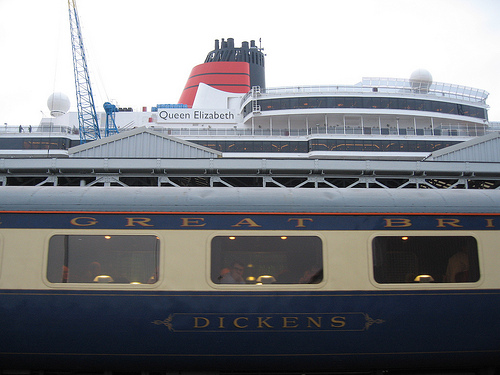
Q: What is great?
A: Britain.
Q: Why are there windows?
A: To see.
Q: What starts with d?
A: Dickens.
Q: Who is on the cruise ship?
A: People.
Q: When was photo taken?
A: Daytime.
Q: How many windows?
A: Three.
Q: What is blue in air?
A: Crane.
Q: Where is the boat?
A: In water.